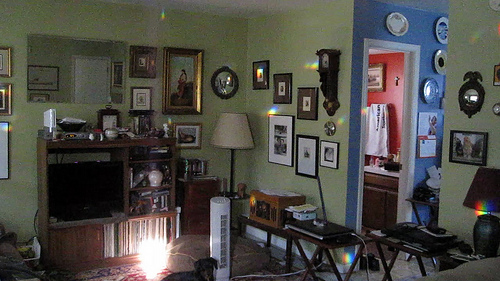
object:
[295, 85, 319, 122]
picture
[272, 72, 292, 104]
picture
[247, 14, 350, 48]
wall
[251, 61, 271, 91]
picture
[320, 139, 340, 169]
picture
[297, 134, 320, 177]
picture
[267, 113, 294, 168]
picture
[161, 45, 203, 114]
picture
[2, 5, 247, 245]
wall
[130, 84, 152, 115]
picture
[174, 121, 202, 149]
picture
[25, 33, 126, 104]
mirror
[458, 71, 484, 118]
mirror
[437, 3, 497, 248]
wall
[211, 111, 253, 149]
lampshade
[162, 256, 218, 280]
dog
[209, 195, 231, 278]
air filter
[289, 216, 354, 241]
laptop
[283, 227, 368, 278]
tv stand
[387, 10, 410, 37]
plate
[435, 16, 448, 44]
plate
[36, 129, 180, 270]
entertainment center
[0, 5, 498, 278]
living room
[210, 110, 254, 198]
lamp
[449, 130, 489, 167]
picture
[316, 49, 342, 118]
clock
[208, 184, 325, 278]
fan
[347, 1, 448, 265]
wall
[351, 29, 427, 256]
entrance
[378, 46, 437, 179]
kitchen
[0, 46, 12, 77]
painting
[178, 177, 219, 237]
shelf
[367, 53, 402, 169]
wall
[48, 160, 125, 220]
tv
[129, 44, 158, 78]
picture